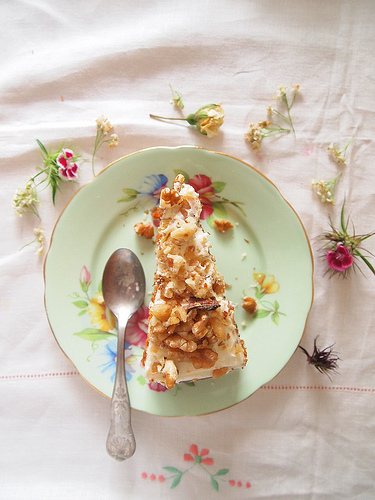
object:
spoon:
[101, 247, 145, 459]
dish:
[43, 145, 314, 417]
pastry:
[140, 173, 248, 389]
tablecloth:
[0, 0, 374, 498]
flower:
[325, 245, 353, 273]